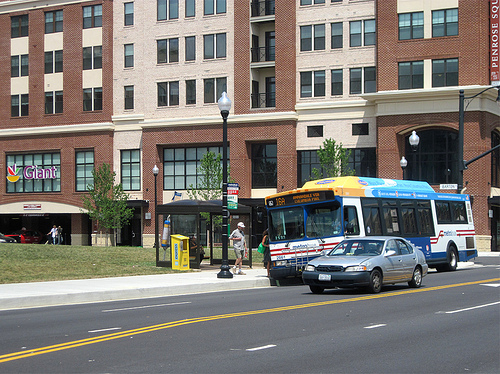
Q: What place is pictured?
A: It is a road.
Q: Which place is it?
A: It is a road.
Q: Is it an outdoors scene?
A: Yes, it is outdoors.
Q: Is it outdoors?
A: Yes, it is outdoors.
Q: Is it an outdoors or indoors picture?
A: It is outdoors.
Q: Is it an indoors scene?
A: No, it is outdoors.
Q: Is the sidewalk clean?
A: Yes, the sidewalk is clean.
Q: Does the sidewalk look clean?
A: Yes, the sidewalk is clean.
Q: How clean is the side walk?
A: The side walk is clean.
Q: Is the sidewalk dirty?
A: No, the sidewalk is clean.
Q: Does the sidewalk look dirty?
A: No, the sidewalk is clean.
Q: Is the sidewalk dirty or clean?
A: The sidewalk is clean.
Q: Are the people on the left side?
A: Yes, the people are on the left of the image.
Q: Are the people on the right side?
A: No, the people are on the left of the image.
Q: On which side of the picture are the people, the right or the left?
A: The people are on the left of the image.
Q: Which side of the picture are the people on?
A: The people are on the left of the image.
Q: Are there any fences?
A: No, there are no fences.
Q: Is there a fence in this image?
A: No, there are no fences.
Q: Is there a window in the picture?
A: Yes, there are windows.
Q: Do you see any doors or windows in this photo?
A: Yes, there are windows.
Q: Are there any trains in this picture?
A: No, there are no trains.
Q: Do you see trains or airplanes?
A: No, there are no trains or airplanes.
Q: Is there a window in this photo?
A: Yes, there are windows.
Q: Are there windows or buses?
A: Yes, there are windows.